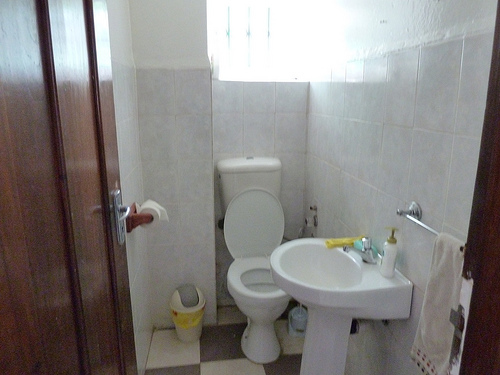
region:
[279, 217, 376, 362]
A sink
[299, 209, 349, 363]
A sink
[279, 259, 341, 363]
A sink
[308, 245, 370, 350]
A sink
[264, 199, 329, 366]
A sink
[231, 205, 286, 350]
toilet in the bathroom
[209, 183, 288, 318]
toilet with lid up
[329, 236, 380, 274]
faucet in the sink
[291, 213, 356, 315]
white sink next to toilet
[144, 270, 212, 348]
trash bin next to toilet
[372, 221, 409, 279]
soap next to the sink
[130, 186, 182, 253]
toilet paper on the wall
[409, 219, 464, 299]
towel on the towel rack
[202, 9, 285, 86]
window above the toilet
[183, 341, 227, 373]
light and dark tile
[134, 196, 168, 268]
toilet paper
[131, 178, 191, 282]
toilet paper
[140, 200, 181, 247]
toilet paper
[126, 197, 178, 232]
TOILET PAPER ON A SPINDLE HOLDER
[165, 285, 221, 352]
GARBAGE CAN HAS YELLOW BAG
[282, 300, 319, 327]
WHITE TOILET BRUSH FOR CLEANING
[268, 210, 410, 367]
THE SINK IS A PEDESTAL STYLE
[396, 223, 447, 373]
HAND TOWEL HANGING ON THE RIGHT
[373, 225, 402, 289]
HAND CREAM FOR SOFT SKIN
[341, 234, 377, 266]
SINGLE HANDLE SING FAUCET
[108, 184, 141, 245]
DOOR HAS A LEVER HANDLE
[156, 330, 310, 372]
BLACK AND WHITE TILES ON FLOOR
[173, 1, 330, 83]
WINDOW ALLOWING SUNLIGHT IN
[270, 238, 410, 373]
a white sink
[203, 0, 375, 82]
light streaming in through a window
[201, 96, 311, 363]
a toilet set in a recessed area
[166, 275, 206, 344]
small trash bin on the ground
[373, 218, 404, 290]
pump bottle on edge of sink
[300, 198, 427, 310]
metal towel bar near sink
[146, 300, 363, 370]
large black and white tiles on floor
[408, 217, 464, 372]
towel hanging from towel bar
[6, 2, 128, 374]
wooden door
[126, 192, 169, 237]
roll of toilet paper